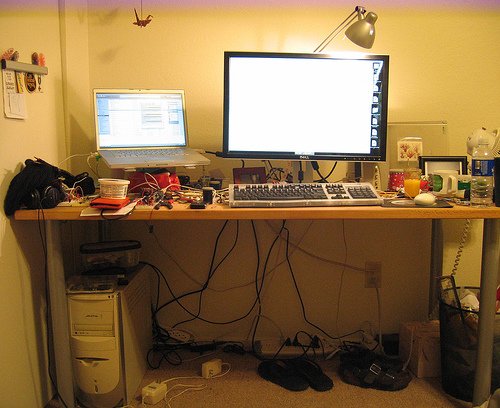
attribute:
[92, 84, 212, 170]
laptop computer — gray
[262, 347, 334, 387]
slippers — black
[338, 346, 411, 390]
sandals — black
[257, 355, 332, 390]
sandals — black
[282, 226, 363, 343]
cord — long, black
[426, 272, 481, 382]
trash bin — black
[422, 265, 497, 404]
can — wire, black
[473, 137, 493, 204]
bottle — water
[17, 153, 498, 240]
desk — brown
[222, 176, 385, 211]
keyboard — white, gray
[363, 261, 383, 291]
outlet — beige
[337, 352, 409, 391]
slippers — brown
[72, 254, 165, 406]
computer — white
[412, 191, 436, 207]
mouse — white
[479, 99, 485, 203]
bottle — water